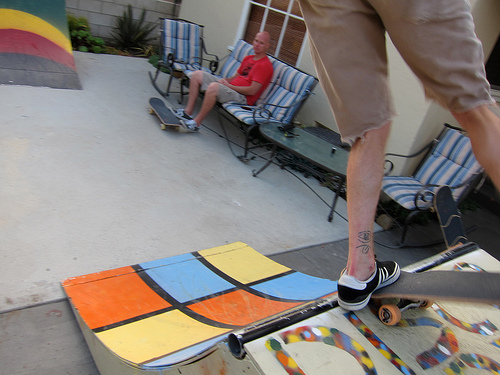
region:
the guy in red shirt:
[162, 14, 316, 214]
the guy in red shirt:
[162, 28, 259, 135]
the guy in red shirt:
[178, 11, 298, 120]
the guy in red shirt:
[179, 31, 255, 91]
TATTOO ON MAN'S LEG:
[355, 228, 372, 257]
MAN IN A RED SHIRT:
[185, 27, 275, 131]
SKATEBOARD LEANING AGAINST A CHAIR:
[426, 182, 471, 255]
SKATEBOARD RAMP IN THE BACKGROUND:
[0, 0, 79, 94]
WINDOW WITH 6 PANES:
[242, 2, 304, 71]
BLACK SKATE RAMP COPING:
[225, 240, 478, 362]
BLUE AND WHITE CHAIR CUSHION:
[157, 14, 218, 99]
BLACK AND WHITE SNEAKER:
[334, 250, 401, 313]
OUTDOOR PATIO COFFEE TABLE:
[252, 109, 373, 228]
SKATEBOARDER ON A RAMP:
[291, 0, 498, 313]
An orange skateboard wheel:
[377, 300, 397, 326]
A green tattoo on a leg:
[350, 225, 370, 255]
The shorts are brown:
[300, 0, 490, 121]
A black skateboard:
[145, 95, 176, 126]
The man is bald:
[250, 30, 266, 51]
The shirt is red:
[226, 50, 266, 100]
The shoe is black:
[332, 251, 398, 302]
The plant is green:
[110, 3, 156, 53]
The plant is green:
[65, 10, 110, 55]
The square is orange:
[58, 260, 172, 327]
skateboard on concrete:
[146, 92, 184, 134]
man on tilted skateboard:
[331, 15, 490, 354]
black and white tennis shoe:
[335, 252, 401, 305]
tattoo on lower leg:
[346, 220, 378, 255]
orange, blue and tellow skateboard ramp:
[60, 240, 344, 372]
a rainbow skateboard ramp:
[7, 6, 90, 103]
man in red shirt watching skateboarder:
[180, 17, 282, 136]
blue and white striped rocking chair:
[145, 0, 218, 112]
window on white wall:
[245, 0, 313, 70]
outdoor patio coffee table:
[250, 113, 345, 219]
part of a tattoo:
[351, 230, 368, 259]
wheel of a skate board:
[391, 310, 396, 317]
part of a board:
[436, 295, 443, 297]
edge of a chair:
[391, 160, 420, 207]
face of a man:
[248, 31, 273, 55]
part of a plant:
[121, 12, 134, 29]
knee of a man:
[208, 75, 228, 98]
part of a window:
[292, 20, 293, 24]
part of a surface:
[116, 148, 150, 213]